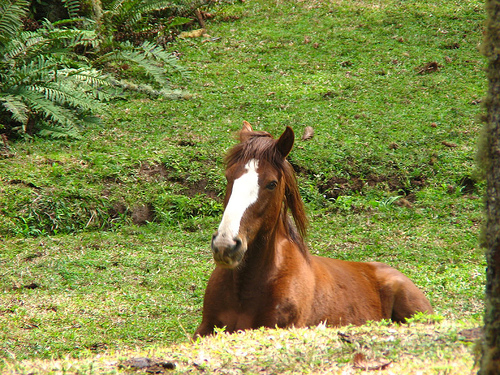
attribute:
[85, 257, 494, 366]
ditch — long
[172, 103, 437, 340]
horse — brown, white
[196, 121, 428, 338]
horse — brown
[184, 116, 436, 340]
horse — white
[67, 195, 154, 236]
mud — brown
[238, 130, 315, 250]
mane — brown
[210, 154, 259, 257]
spot — white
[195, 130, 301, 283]
face — white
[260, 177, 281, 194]
eye — brown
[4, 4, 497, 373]
field — grassy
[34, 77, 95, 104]
leaves — green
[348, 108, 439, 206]
spot — bare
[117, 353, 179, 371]
rock — black